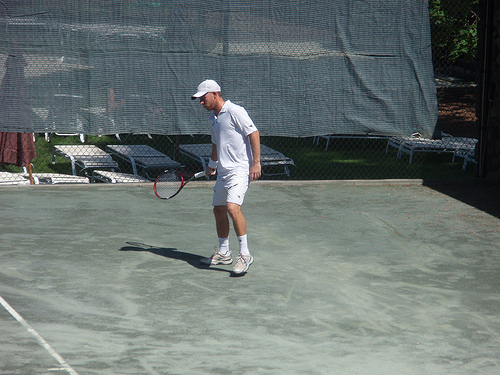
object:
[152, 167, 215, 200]
racket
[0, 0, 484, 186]
net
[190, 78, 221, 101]
hat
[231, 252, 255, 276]
shoes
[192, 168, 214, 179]
white grip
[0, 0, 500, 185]
wall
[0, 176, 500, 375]
court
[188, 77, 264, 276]
man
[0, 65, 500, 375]
ground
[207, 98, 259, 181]
t-shirt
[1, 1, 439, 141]
tarp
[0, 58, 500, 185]
turf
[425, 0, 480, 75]
tree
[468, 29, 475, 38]
green leaves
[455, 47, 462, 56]
green leaves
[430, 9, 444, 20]
green leaves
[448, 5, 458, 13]
green leaves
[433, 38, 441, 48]
green leaves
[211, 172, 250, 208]
shorts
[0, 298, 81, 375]
line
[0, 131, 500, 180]
grass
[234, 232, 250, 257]
socks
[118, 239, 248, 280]
shadow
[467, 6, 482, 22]
branches